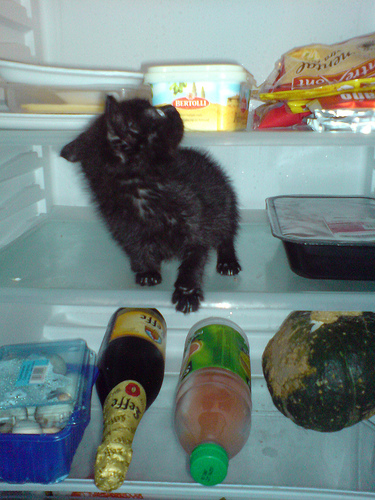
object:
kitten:
[59, 95, 240, 314]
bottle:
[92, 307, 167, 492]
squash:
[261, 311, 375, 431]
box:
[0, 338, 99, 484]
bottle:
[175, 316, 252, 486]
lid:
[189, 443, 229, 487]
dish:
[144, 64, 254, 131]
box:
[265, 195, 375, 281]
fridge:
[0, 1, 375, 500]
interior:
[42, 4, 294, 62]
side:
[150, 318, 164, 388]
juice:
[174, 368, 251, 460]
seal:
[94, 443, 130, 492]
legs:
[174, 245, 208, 290]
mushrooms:
[34, 392, 73, 427]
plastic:
[184, 390, 222, 430]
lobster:
[283, 240, 375, 282]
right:
[340, 198, 374, 242]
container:
[0, 59, 152, 116]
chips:
[306, 91, 375, 119]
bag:
[251, 33, 375, 102]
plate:
[0, 113, 96, 129]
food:
[14, 103, 105, 115]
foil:
[94, 380, 146, 491]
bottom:
[281, 406, 371, 432]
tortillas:
[252, 90, 375, 130]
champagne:
[96, 307, 164, 412]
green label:
[178, 324, 251, 392]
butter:
[151, 83, 251, 132]